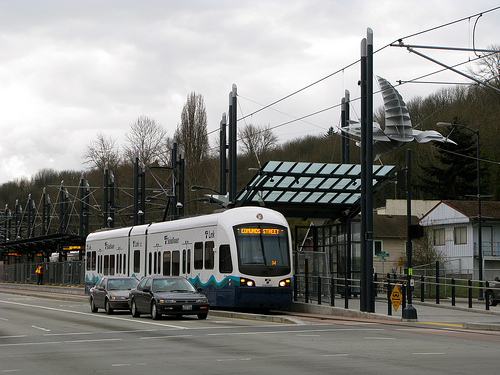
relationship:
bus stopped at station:
[83, 205, 296, 313] [0, 78, 498, 311]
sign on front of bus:
[239, 225, 286, 237] [83, 205, 296, 313]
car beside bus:
[128, 276, 210, 321] [83, 205, 296, 313]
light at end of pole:
[187, 185, 197, 191] [192, 184, 221, 194]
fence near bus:
[297, 218, 354, 315] [74, 197, 316, 323]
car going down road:
[128, 276, 210, 321] [1, 282, 498, 373]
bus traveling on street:
[83, 205, 296, 313] [0, 290, 499, 374]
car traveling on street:
[128, 276, 210, 321] [0, 290, 499, 374]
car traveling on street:
[89, 277, 142, 315] [0, 290, 499, 374]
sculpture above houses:
[339, 72, 462, 169] [318, 177, 498, 309]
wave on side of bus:
[186, 273, 240, 290] [84, 205, 294, 309]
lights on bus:
[238, 277, 293, 289] [84, 205, 294, 309]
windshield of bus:
[237, 231, 290, 266] [84, 205, 294, 309]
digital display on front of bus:
[237, 225, 286, 238] [84, 205, 294, 309]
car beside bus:
[128, 276, 210, 321] [84, 205, 294, 309]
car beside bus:
[89, 275, 144, 314] [84, 205, 294, 309]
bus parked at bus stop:
[83, 201, 298, 314] [233, 161, 399, 318]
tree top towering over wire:
[174, 95, 213, 197] [193, 123, 222, 143]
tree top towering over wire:
[174, 95, 213, 197] [193, 142, 220, 164]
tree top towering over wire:
[127, 121, 163, 162] [193, 123, 222, 143]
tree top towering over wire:
[127, 121, 163, 162] [193, 142, 220, 164]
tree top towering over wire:
[82, 127, 124, 174] [193, 123, 222, 143]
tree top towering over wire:
[82, 127, 124, 174] [193, 142, 220, 164]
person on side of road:
[35, 263, 45, 287] [1, 282, 498, 373]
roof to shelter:
[236, 159, 398, 204] [236, 158, 394, 312]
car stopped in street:
[140, 272, 197, 334] [0, 290, 499, 374]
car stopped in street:
[128, 276, 210, 321] [0, 290, 499, 374]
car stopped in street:
[89, 277, 142, 315] [0, 290, 499, 374]